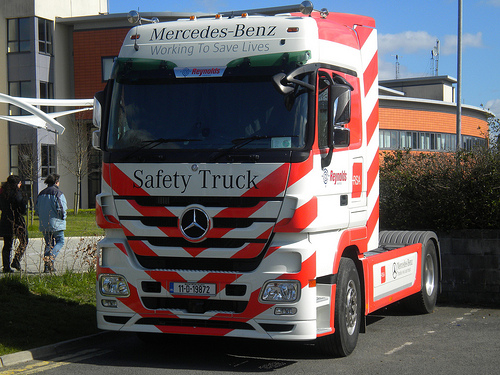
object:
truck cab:
[85, 0, 446, 354]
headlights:
[98, 274, 303, 318]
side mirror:
[328, 82, 353, 147]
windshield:
[108, 59, 312, 161]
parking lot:
[5, 291, 497, 373]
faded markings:
[375, 299, 484, 368]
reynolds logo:
[323, 166, 348, 188]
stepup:
[348, 214, 369, 243]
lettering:
[146, 40, 272, 56]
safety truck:
[126, 166, 265, 193]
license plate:
[171, 278, 216, 299]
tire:
[330, 254, 374, 357]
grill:
[102, 194, 284, 334]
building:
[0, 0, 114, 217]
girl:
[34, 172, 68, 273]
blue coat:
[34, 183, 68, 232]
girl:
[1, 175, 30, 273]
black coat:
[0, 183, 29, 235]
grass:
[0, 272, 96, 356]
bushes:
[377, 146, 500, 231]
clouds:
[371, 30, 483, 58]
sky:
[358, 2, 500, 110]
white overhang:
[0, 92, 98, 136]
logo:
[150, 23, 279, 41]